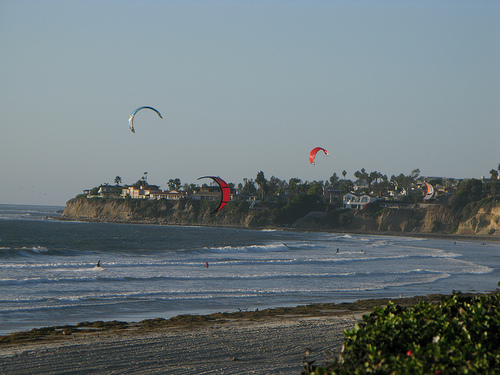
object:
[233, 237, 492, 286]
waves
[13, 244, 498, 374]
beach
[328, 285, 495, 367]
bush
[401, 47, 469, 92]
clouds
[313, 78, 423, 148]
clouds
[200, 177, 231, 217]
kite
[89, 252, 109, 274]
person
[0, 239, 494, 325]
water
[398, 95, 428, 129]
clouds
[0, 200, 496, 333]
ocean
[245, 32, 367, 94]
sky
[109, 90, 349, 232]
sails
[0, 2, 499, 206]
blue sky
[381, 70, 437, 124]
clouds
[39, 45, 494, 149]
sky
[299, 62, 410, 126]
clouds sky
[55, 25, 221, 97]
clouds sky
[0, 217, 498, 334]
water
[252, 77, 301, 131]
cloud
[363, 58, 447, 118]
clouds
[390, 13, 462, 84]
clouds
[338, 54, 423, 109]
clouds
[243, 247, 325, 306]
waves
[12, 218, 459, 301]
water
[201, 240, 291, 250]
sea foam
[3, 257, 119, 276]
sea foam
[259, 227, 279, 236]
sea foam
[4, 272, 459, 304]
sea foam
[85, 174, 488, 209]
houses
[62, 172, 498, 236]
hill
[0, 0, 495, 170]
clouds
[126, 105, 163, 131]
sail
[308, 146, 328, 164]
sail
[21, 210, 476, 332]
ripples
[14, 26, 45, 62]
cloud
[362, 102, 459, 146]
cloud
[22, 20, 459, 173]
air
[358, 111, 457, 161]
cloud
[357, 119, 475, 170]
cloud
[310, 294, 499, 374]
leaves